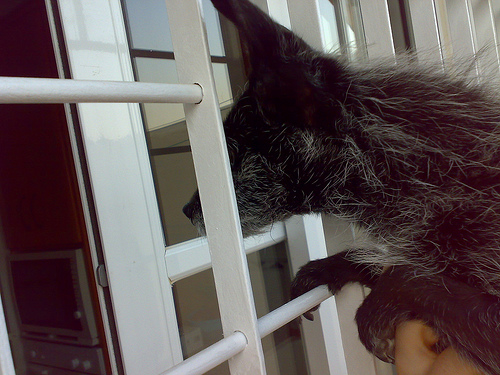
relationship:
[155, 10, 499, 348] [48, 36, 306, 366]
dog looking through window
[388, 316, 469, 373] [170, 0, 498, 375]
hand holding dog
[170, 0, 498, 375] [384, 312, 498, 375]
dog held by person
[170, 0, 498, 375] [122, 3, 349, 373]
dog looking into window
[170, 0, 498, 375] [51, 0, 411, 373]
dog looking in window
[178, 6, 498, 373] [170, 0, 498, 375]
paw on dog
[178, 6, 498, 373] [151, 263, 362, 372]
paw on rail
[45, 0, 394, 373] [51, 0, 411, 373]
white trim on window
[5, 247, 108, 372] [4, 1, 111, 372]
oven in kitchen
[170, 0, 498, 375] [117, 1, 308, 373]
dog looking through window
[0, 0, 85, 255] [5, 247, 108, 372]
cabinet above oven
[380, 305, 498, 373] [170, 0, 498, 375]
fingers under dog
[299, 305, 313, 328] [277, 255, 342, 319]
toenails on paw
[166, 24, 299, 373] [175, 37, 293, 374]
board holding posts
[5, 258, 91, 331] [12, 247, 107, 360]
screen on monitor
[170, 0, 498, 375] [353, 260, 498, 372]
dog being held by person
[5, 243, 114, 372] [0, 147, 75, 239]
device against wall